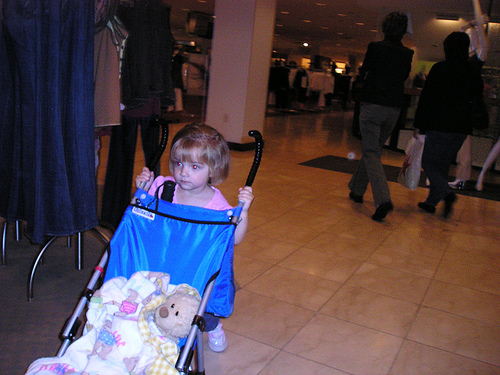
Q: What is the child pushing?
A: A stroller.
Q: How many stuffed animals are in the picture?
A: One.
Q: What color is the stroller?
A: Blue.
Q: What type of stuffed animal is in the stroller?
A: Bear.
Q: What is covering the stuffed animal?
A: Blanket.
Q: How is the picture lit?
A: Indoor lighting.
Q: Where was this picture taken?
A: Lobby.